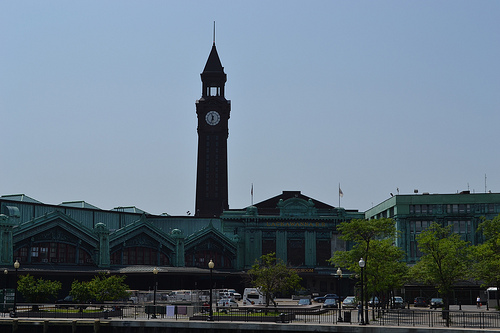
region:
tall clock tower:
[167, 10, 249, 272]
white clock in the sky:
[195, 104, 230, 130]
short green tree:
[247, 250, 305, 315]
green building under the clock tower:
[7, 170, 410, 325]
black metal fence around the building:
[350, 300, 479, 331]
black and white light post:
[199, 255, 221, 326]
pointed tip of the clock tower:
[194, 13, 229, 51]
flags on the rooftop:
[329, 170, 356, 210]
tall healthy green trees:
[342, 199, 414, 327]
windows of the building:
[19, 244, 99, 267]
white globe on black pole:
[352, 253, 377, 321]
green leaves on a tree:
[242, 249, 299, 330]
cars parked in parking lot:
[278, 284, 446, 326]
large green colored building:
[0, 192, 342, 284]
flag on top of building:
[308, 175, 355, 222]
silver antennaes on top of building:
[360, 164, 490, 214]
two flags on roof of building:
[227, 165, 357, 222]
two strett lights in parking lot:
[307, 247, 381, 319]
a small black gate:
[312, 301, 497, 331]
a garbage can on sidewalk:
[312, 289, 372, 331]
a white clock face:
[200, 107, 223, 127]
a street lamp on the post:
[354, 250, 371, 269]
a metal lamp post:
[353, 264, 368, 328]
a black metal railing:
[1, 298, 499, 331]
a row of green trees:
[324, 210, 419, 327]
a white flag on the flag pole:
[333, 179, 346, 198]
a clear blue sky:
[0, 0, 499, 222]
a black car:
[425, 292, 446, 311]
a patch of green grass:
[191, 302, 283, 319]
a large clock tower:
[188, 15, 233, 217]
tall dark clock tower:
[194, 19, 230, 216]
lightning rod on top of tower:
[212, 21, 218, 45]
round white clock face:
[204, 110, 221, 127]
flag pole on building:
[336, 179, 346, 205]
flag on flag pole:
[338, 186, 347, 197]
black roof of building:
[236, 190, 344, 212]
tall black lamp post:
[207, 259, 216, 321]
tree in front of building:
[245, 253, 310, 315]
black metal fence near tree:
[0, 304, 341, 327]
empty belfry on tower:
[201, 76, 227, 97]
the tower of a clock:
[196, 16, 234, 98]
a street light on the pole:
[356, 253, 370, 270]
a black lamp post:
[357, 265, 367, 323]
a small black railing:
[0, 299, 499, 331]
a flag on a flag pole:
[334, 180, 349, 199]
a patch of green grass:
[40, 301, 102, 313]